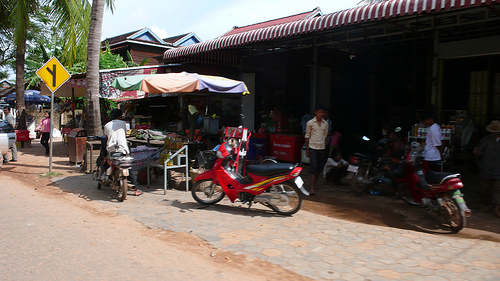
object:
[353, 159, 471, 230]
motorcycles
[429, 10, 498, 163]
markets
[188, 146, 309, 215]
motorcycle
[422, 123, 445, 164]
shirts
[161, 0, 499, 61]
fabric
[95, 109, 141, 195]
person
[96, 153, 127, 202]
motorbike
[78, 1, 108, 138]
palm tree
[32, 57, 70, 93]
traffic sign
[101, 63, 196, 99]
panel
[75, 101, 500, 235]
side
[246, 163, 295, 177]
black seat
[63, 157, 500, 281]
center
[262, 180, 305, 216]
back tire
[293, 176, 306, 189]
plate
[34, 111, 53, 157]
"person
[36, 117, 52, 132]
shirt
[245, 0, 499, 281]
right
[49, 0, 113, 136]
trees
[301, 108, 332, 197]
man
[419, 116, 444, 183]
man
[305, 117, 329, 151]
shirt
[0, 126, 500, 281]
street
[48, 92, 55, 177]
pole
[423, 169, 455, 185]
black pants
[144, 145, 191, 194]
chair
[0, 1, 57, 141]
tree